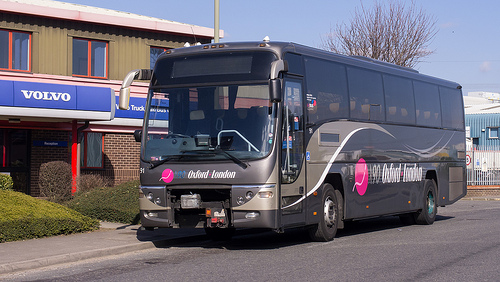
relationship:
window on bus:
[436, 78, 470, 133] [135, 42, 474, 256]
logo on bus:
[352, 153, 373, 198] [135, 42, 474, 256]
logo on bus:
[157, 164, 173, 185] [135, 42, 474, 256]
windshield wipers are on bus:
[149, 148, 254, 173] [135, 42, 474, 256]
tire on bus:
[308, 181, 342, 241] [135, 42, 474, 256]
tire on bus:
[411, 175, 440, 221] [135, 42, 474, 256]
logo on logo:
[20, 85, 76, 104] [20, 85, 76, 104]